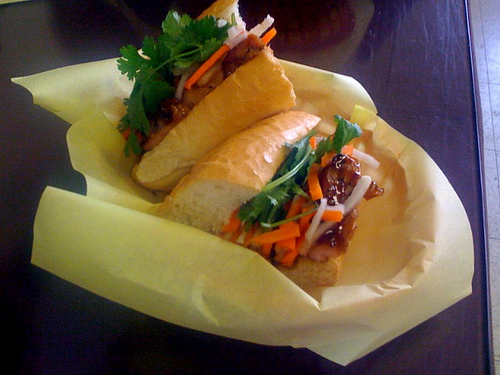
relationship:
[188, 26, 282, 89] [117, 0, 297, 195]
carrots in sandwich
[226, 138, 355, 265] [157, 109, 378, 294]
carrots in sandwich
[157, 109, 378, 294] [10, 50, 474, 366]
sandwich on paper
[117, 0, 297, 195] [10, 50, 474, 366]
sandwich on paper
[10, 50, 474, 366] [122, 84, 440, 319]
paper in bowl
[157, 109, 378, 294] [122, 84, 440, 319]
sandwich in bowl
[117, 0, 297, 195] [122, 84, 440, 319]
sandwich in bowl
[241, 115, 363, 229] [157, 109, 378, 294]
greens in sandwich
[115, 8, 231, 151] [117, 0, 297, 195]
greens in sandwich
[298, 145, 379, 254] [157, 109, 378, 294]
onions in sandwich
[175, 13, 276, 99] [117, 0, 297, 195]
onions in sandwich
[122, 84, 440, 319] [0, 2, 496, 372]
bowl on table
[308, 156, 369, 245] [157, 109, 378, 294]
meat in sandwich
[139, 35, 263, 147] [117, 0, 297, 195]
meat in sandwich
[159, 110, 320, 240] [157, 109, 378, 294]
bread in sandwich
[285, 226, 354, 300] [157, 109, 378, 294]
bread in sandwich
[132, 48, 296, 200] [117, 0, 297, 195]
bread in sandwich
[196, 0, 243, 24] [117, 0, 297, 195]
bread in sandwich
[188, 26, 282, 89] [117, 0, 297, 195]
carrots on sandwich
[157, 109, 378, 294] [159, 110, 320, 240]
sandwich on bread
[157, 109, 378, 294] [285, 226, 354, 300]
sandwich on bread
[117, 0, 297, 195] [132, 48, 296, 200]
sandwich on bread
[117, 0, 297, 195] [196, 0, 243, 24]
sandwich on bread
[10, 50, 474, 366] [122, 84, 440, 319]
paper on bowl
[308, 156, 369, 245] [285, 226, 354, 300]
meat between bread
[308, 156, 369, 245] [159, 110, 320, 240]
meat between bread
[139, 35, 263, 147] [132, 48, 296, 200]
meat between bread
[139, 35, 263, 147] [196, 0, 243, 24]
meat between bread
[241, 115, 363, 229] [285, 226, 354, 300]
greens between bread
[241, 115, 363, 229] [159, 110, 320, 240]
greens between bread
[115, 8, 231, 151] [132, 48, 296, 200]
greens between bread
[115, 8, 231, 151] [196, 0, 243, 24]
greens between bread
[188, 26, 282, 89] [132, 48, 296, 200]
carrots between bread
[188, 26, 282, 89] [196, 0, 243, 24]
carrots between bread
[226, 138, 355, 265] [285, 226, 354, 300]
carrots between bread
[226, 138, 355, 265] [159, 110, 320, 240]
carrots between bread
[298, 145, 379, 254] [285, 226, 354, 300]
onions between bread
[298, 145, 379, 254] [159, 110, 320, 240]
onions between bread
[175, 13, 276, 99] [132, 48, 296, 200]
onions between bread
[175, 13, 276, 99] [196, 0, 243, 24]
onions between bread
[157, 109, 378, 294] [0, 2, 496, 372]
sandwich on table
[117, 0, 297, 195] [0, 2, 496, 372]
sandwich on table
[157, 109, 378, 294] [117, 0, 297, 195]
sandwich behind sandwich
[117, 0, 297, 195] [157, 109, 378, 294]
sandwich behind sandwich